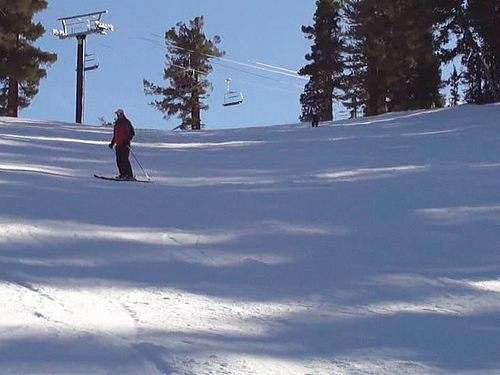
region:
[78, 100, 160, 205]
a lone skieer dressed in a red jacket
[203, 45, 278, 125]
a ski lift on a sunny day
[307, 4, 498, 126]
trees lining a ski slope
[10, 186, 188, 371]
a snowy hill dappled in sunlight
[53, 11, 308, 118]
a ski lift support crossing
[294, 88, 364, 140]
a skier swooping the course at a distance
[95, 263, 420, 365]
fresh powdery snow with ski tracks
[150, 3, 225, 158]
a long tree on a snowy hill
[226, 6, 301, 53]
a clear blue sky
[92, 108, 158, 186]
a skier grasping his ski poles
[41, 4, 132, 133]
Ski lift support pole.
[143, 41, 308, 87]
Wires supporting ski lifts.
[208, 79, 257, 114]
A chairlift attached to ski lift wires.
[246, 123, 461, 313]
Shadows in the snow from trees.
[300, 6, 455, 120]
Several large green trees.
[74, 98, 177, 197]
A skier standing in the snow.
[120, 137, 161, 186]
Ski pole.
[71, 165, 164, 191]
Skis in the snow.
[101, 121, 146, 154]
Red ski jacket.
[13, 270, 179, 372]
Tracks left by previous skiers.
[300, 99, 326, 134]
a skier on a ski slope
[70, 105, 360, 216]
the skier is traversing the ski run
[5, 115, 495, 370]
shadows are covering the ski slope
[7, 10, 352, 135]
a chair ski lift is on the top of the mountain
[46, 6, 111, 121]
a pole support holds up the lift cables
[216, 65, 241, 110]
a ski chair attached to the cable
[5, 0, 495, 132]
pine trees on top of the mountain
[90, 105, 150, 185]
the skier has a white cap on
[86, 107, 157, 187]
the snow skier is holding two poles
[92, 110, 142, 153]
the skier has a black and red ski jacket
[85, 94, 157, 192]
Man wearing black suit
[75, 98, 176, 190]
Man wearing red and black coat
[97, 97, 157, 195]
Pants of man is black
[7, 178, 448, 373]
Shadow of trees cast on the snow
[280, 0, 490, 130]
Trees on the snow truck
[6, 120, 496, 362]
Snow cover the field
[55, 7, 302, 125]
Sky is blue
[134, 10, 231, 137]
Green tree in the middle of snow truck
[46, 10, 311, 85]
Wires on rotating cable car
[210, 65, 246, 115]
Cable car on wires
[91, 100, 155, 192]
One man on ski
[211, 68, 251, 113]
Ski lift in the distance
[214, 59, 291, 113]
Ski lift and ski lift cables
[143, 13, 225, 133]
Tree in the background with snow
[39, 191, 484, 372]
Shadows on white snow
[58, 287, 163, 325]
White snow on side of mountain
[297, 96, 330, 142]
Person in distance on snow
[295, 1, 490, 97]
Trees in the distance on snow capped mountain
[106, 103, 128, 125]
Man in cap and glasses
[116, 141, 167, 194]
Ski pole and snow